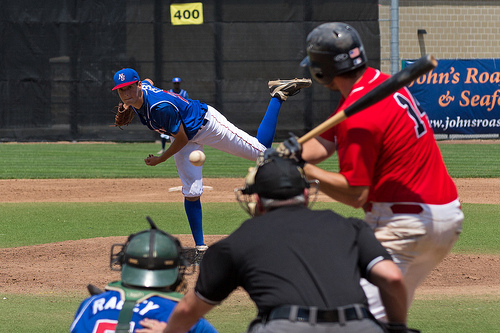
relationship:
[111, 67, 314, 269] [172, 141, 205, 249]
picher has leg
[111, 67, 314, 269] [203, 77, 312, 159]
picher has leg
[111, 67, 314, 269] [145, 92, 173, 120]
picher has shoulder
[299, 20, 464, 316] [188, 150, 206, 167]
player swinging at ball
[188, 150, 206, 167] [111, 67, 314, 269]
ball thrown to picher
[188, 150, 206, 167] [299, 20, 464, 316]
ball thrown to player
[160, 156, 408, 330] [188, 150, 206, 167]
umpire watching ball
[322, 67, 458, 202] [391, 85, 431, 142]
shirt has number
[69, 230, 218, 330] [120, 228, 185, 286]
catcher has helmet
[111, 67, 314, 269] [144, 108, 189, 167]
picher has arm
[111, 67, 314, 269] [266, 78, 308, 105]
picher wearing cleat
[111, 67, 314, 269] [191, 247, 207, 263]
picher wearing cleat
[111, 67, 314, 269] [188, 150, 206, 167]
picher throwing ball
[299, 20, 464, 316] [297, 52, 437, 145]
player swinging bat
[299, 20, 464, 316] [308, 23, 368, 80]
player wearing helmet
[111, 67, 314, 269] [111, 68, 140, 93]
picher wearing cap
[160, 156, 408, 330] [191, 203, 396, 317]
umpire wearing man shirt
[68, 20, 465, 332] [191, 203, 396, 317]
people wearing man shirt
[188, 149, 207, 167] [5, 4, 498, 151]
ball in stadium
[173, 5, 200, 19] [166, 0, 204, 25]
number on sign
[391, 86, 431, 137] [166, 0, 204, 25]
number on sign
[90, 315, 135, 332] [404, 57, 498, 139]
number on sign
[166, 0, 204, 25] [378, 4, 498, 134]
sign on wall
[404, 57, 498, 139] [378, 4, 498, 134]
sign on wall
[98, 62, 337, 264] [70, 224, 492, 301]
picher on mound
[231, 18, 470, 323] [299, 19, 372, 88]
batter wears helmet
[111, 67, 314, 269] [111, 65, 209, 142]
picher wears blue costume